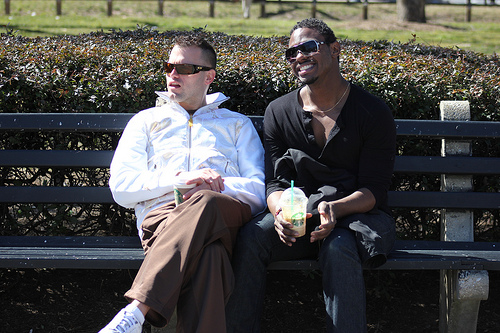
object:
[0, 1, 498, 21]
walking path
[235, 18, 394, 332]
people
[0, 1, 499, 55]
grassy area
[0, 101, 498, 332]
bench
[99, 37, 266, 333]
person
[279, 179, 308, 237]
container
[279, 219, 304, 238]
beverage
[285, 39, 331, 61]
sunglasses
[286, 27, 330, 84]
face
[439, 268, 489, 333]
stone leg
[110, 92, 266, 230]
jacket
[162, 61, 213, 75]
sunglasses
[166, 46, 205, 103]
face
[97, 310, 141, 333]
shoe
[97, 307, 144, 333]
foot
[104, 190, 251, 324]
legs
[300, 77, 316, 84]
goatee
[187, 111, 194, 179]
zipper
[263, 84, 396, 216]
shirt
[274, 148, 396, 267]
jacket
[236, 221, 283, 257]
lap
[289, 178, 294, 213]
straw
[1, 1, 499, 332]
scene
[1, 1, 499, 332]
outside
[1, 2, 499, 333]
day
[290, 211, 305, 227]
starbucks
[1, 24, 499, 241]
hedges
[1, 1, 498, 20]
distance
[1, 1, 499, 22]
fence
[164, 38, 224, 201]
light skin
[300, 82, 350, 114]
necklace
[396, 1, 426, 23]
tree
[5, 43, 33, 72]
leaves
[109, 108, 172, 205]
arms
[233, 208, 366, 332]
pants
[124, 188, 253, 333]
pants